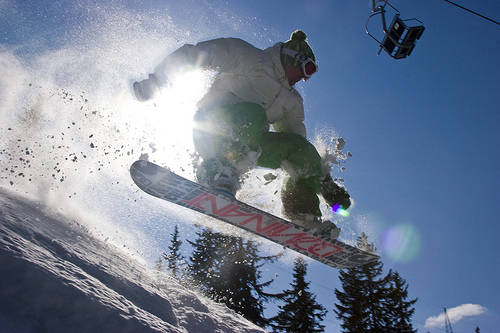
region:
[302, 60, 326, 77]
White framed snow goggles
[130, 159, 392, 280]
Long snowboard with red writing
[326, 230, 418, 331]
Tall green pine tree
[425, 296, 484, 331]
White cloud in sky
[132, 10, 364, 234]
Man on long snow board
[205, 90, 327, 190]
Green snow pants on man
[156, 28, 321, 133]
White winter jacket on man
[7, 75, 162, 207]
Bits of snow in air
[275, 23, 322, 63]
Hat with pom pom on man's head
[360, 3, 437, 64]
Metal ski lift chair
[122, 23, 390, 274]
snowboarder jumping in air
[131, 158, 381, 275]
bottom of snowboard with text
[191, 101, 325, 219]
green pants of snowboarder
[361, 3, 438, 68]
ski lift overhead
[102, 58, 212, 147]
sun shining through the snow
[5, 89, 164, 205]
snow being kicked up by snowboarder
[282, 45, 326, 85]
ski goggles of snowboarder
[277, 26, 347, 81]
knit cap of snowboarder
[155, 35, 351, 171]
white jacket of snowboarder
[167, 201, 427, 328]
trees behind snowboarder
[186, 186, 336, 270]
red writing on bottom of snow board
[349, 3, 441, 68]
metal ski lift in air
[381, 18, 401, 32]
sticker on back of ski lift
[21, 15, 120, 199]
cloud of snow in air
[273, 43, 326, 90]
red and white safety goggles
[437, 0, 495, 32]
metal ski lift wire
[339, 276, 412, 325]
tree with green leaves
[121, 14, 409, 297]
snow boarder jumping in air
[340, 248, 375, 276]
design on bottom of snowboard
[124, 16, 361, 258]
snowboarder in white jacket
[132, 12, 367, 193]
man wearing a white jacket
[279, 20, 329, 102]
man wearing white goggles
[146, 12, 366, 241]
man wearing green pants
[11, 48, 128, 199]
white snow in the air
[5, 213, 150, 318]
white snow on the ground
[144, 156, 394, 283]
snowboard in the air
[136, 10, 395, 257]
man snowboarding in the air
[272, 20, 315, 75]
man wearing green beanie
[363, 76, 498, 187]
bright blue cloudless sky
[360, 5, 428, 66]
black bench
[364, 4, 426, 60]
A ski lift chair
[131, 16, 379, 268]
A man on a snowboard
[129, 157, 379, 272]
A snowboard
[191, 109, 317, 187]
green pants on the snowboarder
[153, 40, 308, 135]
White jacket on the snowboarder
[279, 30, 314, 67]
A green beanie on the snowboarder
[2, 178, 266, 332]
A snow covered hill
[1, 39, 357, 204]
Some snow in the air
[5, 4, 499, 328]
A clear, blue sky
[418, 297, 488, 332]
A cloud in the sky